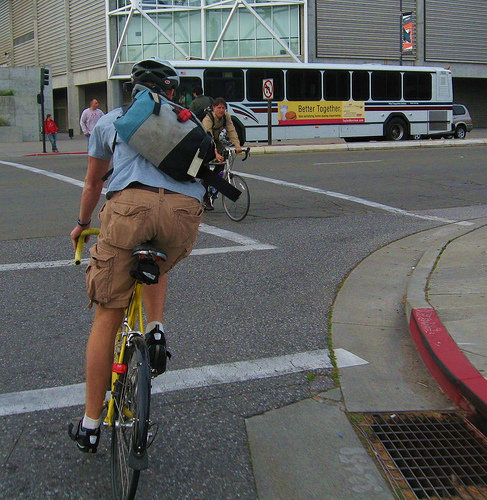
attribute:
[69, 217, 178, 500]
bike — yellow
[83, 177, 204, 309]
shorts — tan, brown, cargo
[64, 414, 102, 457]
shoe — black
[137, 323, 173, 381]
shoe — black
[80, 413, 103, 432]
sock — white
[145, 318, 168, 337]
sock — white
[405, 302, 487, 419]
curb — red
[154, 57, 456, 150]
bus — white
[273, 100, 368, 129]
sign — yellow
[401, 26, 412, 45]
dog — black, white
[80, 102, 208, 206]
shirt — light blue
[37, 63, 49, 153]
pole — light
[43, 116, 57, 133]
sweatshirt — red